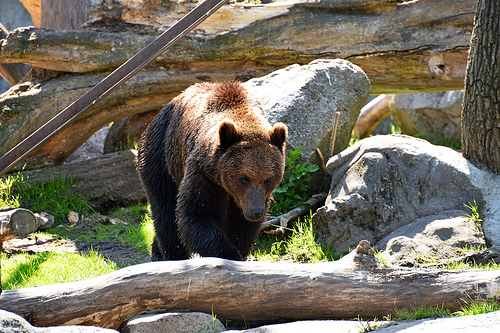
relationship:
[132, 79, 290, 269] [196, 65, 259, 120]
bear in fur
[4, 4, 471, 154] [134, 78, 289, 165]
logs behind bear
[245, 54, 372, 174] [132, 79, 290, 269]
boulder behind bear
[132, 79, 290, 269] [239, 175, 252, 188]
bear has eyes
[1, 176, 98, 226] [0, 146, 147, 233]
green grass against logs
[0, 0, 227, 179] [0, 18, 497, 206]
bar in front of logs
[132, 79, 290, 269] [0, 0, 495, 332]
bear in zoo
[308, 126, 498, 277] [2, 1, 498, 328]
boulder in pen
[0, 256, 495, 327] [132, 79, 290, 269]
log by bear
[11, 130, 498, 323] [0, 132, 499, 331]
grass on ground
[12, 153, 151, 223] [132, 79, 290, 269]
log behind bear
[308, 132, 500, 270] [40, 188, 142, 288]
boulder on ground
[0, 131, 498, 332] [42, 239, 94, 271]
grass on ground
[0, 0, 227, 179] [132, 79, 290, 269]
bar beside bear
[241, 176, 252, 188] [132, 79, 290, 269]
eye of bear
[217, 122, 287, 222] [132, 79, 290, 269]
head of a bear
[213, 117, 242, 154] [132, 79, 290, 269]
ear of a bear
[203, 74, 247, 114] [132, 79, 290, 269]
fur of a bear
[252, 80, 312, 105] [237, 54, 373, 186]
reflection on a boulder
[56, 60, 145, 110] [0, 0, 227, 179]
rust on an bar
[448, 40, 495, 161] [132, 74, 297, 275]
tree stands near bear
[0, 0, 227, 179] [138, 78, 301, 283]
bar near bear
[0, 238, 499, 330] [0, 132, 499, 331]
log on ground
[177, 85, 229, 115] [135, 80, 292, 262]
fur on bears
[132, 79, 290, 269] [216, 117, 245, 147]
bear has ear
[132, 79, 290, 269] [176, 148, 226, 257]
bear has leg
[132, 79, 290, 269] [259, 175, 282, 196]
bear has eye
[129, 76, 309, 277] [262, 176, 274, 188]
bear has eye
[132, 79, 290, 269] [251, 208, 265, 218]
bear has nose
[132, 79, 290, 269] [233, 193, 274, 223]
bear has mouth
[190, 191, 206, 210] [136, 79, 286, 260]
dirt on fur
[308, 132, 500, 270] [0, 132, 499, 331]
boulder on ground